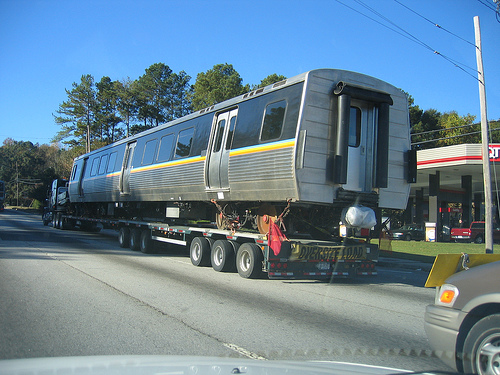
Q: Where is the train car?
A: On a flatbed trailer.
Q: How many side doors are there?
A: 6.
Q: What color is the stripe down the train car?
A: Yellow.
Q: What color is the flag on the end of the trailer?
A: Red.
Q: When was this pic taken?
A: During the day.